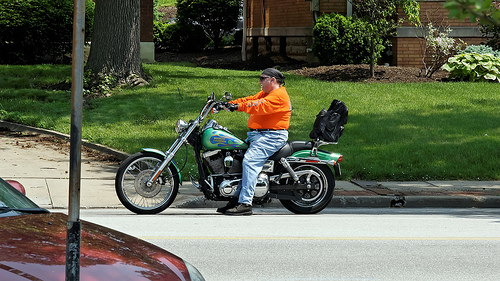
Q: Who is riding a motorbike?
A: A man.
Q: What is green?
A: Grass.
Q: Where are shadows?
A: On the grass.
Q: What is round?
A: Tires.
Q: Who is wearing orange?
A: Rider.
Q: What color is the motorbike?
A: Green.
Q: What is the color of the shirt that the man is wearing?
A: Orange.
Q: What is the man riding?
A: Motorcycle.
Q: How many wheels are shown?
A: Two.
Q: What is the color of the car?
A: Red.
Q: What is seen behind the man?
A: Grass.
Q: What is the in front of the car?
A: Pole.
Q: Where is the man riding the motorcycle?
A: Street.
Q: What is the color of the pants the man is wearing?
A: Blue.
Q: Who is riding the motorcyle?
A: A man.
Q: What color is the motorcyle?
A: Green.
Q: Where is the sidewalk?
A: Along side of street.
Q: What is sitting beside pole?
A: A car.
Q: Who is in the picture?
A: A man.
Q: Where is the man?
A: On a motorcycle.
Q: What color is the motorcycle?
A: Green.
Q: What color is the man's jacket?
A: Orange.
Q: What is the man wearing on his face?
A: Sunglasses.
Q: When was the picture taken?
A: Daytime.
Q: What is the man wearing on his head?
A: A cap.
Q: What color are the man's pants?
A: Blue.